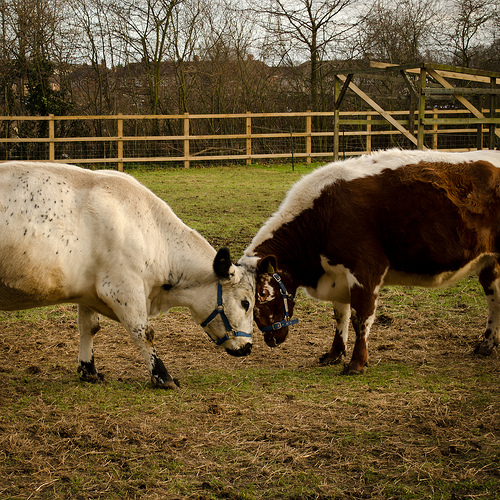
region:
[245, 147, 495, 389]
A brown and white cow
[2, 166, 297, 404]
A white and black cow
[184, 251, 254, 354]
A blue harness on a white and black cow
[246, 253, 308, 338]
A harness of blue on a brown and white cow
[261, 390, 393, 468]
Loose hay lies here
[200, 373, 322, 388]
Green pasture grass peaks through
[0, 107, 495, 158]
A fence of wood and steel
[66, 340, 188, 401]
A pair of hooves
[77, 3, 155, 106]
Bald trees that are missing their leaves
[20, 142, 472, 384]
A pair of cows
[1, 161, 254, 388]
large white cow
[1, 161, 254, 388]
large cow on the left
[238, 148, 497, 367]
large brown and white cow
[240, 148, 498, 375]
large cow on the right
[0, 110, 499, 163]
wooden fence in the background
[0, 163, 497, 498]
green and dried grass on the ground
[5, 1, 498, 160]
group of trees beyond fence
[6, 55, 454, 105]
buildings behind trees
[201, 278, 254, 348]
blue harness on cow's head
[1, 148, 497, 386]
two cows facing each other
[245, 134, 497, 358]
The cow is brown and white.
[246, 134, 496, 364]
The cow is standing.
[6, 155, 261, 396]
The cow is white.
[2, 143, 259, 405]
The cow is standing.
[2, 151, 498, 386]
The cows are butting heads.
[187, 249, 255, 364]
The cow has a black muzzle.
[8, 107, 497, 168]
The fence is wooden.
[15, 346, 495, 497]
The grass is brown and green.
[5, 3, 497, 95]
The trees are bare.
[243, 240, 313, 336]
The cow has a blue muzzle on.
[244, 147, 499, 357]
a white and brown cow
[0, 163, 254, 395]
a white a black cow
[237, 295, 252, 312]
the eye of a cow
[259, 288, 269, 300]
the eye of a cow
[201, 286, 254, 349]
a blue muzzle on a cow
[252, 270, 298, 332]
a blue muzzle on a cow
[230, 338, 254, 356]
the nose of a cow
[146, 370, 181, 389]
the hoof of a cow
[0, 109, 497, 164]
a stretch of wooden fencing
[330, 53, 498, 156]
a wooden structure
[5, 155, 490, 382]
two cows have heads together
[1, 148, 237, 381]
cow on left is white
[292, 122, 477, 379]
cow on right is brown and white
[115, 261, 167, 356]
cow has white legs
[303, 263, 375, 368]
cow has spotted legs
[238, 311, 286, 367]
cows have brown noses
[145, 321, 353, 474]
ground under cows is brown and bare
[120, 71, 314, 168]
brown fence behind cows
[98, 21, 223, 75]
bare trees behind cows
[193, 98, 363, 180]
fence is wooden